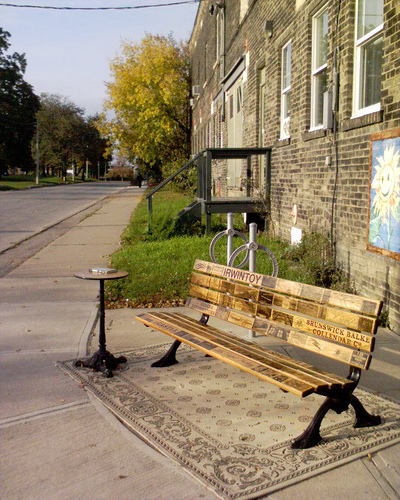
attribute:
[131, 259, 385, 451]
bench — wooden, empty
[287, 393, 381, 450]
legs — black, metal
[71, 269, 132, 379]
table — small, round, circular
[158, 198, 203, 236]
stairs — wooden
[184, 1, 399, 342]
wall — bricked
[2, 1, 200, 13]
wire — hanging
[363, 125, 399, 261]
painting — sunflower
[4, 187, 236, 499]
sidewalk — concrete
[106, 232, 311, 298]
grass — green, trimmed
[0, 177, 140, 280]
road — clear